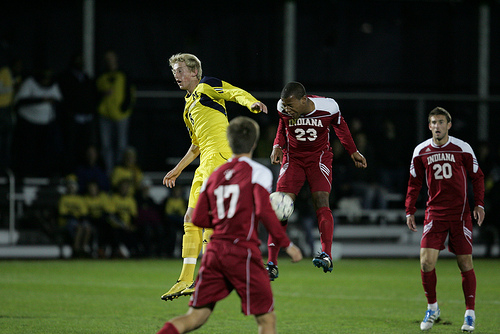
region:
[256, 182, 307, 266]
the hand of a person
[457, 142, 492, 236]
the hand of a person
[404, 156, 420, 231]
the hand of a person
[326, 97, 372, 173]
the hand of a person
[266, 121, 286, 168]
the hand of a person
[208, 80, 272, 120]
the hand of a person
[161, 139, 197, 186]
the hand of a person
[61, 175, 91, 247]
a person is sitting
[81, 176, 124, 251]
a person is sitting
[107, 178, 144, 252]
a person is sitting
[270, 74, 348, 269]
a soccer player kicking a ball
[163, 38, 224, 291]
a jumping soccer player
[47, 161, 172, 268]
soccer players waiting for there turn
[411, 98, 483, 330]
an exhausted soccer player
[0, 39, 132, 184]
the audience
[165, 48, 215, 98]
a soccer players face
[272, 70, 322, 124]
a black soccer player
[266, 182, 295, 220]
a soccer ball being kicked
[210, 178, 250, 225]
a shirt with a number on it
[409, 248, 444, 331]
a soccer players leg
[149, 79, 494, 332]
three players have red uniforms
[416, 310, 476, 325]
the player has blue laces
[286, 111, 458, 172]
the uniforms says INDIANA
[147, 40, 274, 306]
the player has a yellow uniform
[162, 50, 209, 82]
the man is blond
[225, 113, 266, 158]
the man has brown hair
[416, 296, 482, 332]
the man has white shoes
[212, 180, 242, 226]
the mans uniform is number 17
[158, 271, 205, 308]
the man is wearing yellow shoes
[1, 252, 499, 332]
the grass is green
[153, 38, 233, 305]
soccer player wearing all yellow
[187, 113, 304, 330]
soccer player number seventeen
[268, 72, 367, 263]
soccer player number twenty three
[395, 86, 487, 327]
soccer player number twenty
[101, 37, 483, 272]
men playing a soccer game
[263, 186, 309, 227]
black and white soccer ball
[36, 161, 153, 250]
yellow team members on the bench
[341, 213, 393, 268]
empty silver benches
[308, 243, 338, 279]
black and white soccer cleats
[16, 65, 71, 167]
spectator to a soccer game wearing a white shirt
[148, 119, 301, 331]
a player in the field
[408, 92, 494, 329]
a player in the field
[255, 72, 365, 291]
a player in the field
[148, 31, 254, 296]
a player in the field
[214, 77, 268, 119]
the hand of the player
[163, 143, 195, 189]
the hand of the player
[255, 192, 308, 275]
the hand of the player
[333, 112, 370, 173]
the hand of the player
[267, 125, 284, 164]
the hand of the player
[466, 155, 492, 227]
the hand of the player